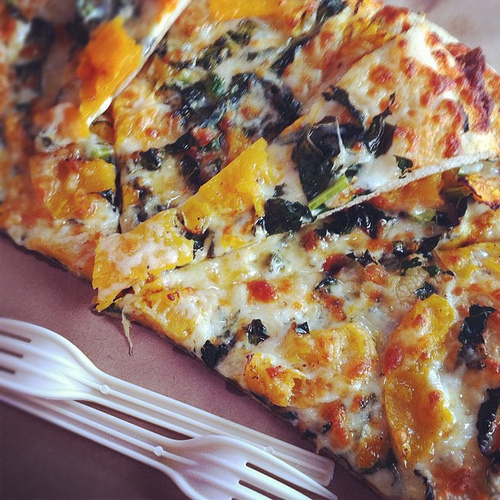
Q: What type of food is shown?
A: Pizza.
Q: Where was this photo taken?
A: Restaraunt.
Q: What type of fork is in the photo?
A: Plastic.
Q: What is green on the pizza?
A: Spinach.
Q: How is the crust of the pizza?
A: Thin.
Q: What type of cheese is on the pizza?
A: Mozzarella.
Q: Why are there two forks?
A: Two peolple eating.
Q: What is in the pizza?
A: Papers.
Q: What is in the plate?
A: Pieces.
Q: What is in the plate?
A: Fork.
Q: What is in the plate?
A: Pizza.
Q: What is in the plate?
A: Fork.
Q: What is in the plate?
A: Cheese.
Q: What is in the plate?
A: Plastic.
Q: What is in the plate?
A: Cheese.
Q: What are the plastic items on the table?
A: Forks.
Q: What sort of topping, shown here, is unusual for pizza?
A: The peach slices.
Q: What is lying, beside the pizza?
A: Two forks.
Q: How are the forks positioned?
A: In opposing directions, beside each other.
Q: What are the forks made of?
A: Plastic.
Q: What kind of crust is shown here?
A: Flatbread.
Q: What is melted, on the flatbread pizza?
A: Cheese.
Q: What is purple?
A: The surface, beneath the pizza and forks.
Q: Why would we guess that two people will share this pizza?
A: There are two forks.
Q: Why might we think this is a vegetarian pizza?
A: Because there is no obvious meat toppings shown.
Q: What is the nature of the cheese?
A: Melted.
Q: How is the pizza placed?
A: Sliced.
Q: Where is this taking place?
A: Indoors.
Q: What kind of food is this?
A: Pizza.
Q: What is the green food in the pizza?
A: Spinach.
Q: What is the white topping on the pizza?
A: Cheese.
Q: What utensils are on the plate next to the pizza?
A: Forks.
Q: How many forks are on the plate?
A: Two.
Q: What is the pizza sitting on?
A: Lavender surface.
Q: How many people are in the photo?
A: None.